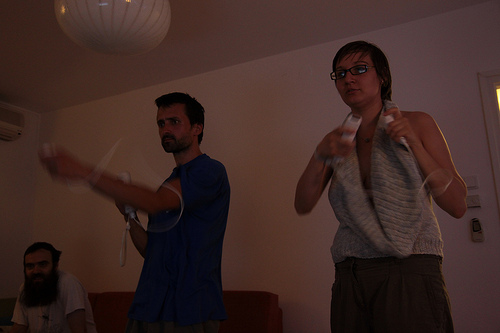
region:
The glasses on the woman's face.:
[326, 62, 373, 82]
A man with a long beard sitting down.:
[15, 240, 66, 311]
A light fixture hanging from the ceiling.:
[52, 0, 172, 60]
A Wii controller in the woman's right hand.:
[336, 108, 363, 158]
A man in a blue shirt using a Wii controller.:
[36, 92, 246, 332]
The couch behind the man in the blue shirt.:
[3, 290, 283, 331]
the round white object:
[54, 1, 171, 57]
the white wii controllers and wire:
[315, 112, 451, 210]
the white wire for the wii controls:
[412, 165, 458, 207]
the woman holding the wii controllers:
[294, 40, 467, 332]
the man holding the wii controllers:
[39, 92, 231, 332]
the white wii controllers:
[36, 135, 186, 268]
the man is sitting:
[11, 240, 99, 330]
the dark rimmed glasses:
[330, 62, 377, 79]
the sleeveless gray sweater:
[328, 99, 443, 262]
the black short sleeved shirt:
[129, 150, 230, 325]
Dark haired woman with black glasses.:
[292, 39, 468, 331]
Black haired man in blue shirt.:
[39, 92, 232, 332]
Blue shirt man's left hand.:
[37, 146, 81, 181]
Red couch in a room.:
[0, 288, 285, 332]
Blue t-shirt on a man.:
[130, 152, 227, 324]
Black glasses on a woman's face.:
[328, 62, 380, 82]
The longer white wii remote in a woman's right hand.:
[327, 113, 361, 168]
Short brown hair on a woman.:
[330, 41, 391, 105]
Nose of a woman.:
[343, 72, 355, 85]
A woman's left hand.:
[385, 105, 416, 146]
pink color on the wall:
[216, 85, 275, 135]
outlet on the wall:
[467, 213, 491, 249]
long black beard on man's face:
[10, 271, 70, 306]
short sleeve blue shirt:
[121, 149, 255, 298]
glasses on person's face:
[314, 60, 386, 80]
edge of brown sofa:
[238, 271, 290, 321]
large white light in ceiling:
[48, 3, 200, 65]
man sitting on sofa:
[11, 232, 111, 319]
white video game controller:
[328, 104, 457, 241]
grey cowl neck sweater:
[318, 95, 447, 274]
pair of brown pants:
[323, 248, 457, 331]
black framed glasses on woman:
[322, 56, 384, 86]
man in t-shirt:
[31, 78, 233, 330]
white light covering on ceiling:
[44, 0, 185, 68]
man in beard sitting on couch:
[5, 234, 290, 331]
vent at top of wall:
[2, 99, 28, 146]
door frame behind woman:
[468, 63, 498, 212]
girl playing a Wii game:
[273, 30, 490, 323]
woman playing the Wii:
[278, 24, 479, 294]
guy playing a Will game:
[45, 84, 290, 310]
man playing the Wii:
[33, 67, 279, 322]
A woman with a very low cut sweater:
[305, 81, 420, 299]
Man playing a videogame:
[44, 97, 236, 296]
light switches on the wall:
[460, 182, 492, 252]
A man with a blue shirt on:
[112, 132, 229, 312]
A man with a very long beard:
[20, 235, 65, 317]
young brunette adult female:
[282, 35, 476, 332]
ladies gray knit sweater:
[319, 96, 451, 266]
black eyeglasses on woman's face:
[328, 59, 393, 86]